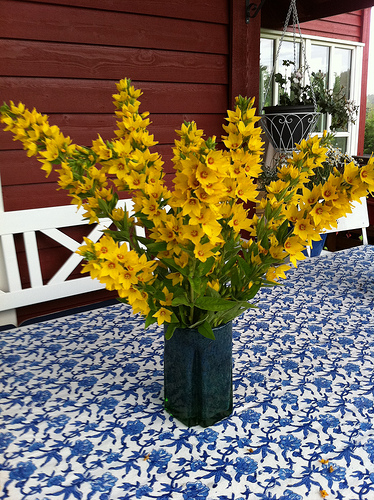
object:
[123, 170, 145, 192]
flower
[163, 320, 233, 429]
vase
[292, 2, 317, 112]
chain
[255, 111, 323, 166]
basket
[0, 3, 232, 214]
wall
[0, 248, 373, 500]
table